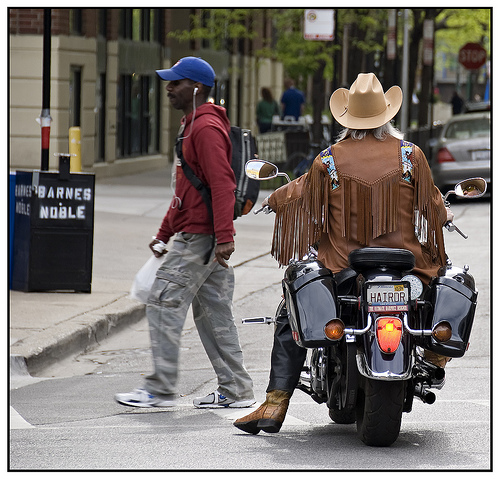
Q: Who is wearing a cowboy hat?
A: Man on motorbike.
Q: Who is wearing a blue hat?
A: Man walking.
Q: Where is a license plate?
A: On back of motorbike.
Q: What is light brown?
A: Cowboy hat.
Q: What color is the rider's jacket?
A: Brown.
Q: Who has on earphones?
A: Man with blue hat.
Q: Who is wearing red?
A: Man walking.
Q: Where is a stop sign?
A: In the distance.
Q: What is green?
A: Trees.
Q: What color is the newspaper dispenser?
A: Black.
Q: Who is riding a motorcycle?
A: A man.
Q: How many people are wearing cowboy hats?
A: One.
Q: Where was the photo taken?
A: Downtown.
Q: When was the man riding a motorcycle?
A: Sometime throughout the day.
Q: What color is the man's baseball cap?
A: Blue.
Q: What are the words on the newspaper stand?
A: BARNES NOBLE.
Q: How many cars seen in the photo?
A: One.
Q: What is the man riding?
A: A motorcycle.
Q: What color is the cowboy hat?
A: Tan.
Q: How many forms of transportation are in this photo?
A: 2.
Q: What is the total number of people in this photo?
A: 4.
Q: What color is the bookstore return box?
A: It is black.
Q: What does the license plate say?
A: HAIRDR.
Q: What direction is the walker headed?
A: Left.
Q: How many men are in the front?
A: 2.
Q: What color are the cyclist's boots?
A: Brown.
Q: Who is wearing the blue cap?
A: The walker.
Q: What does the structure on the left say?
A: Barnes Noble.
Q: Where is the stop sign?
A: In the distance on the right.